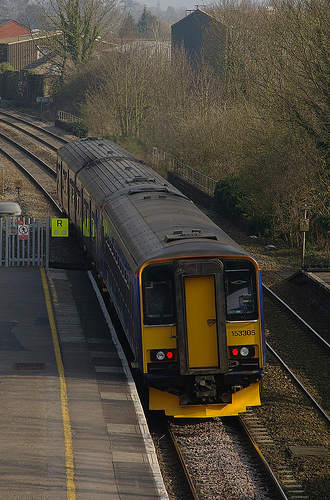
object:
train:
[56, 130, 266, 415]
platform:
[20, 263, 127, 493]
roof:
[126, 147, 195, 253]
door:
[173, 258, 227, 375]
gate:
[8, 213, 50, 271]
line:
[36, 264, 89, 355]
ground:
[27, 330, 116, 437]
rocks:
[194, 437, 257, 497]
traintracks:
[159, 426, 308, 499]